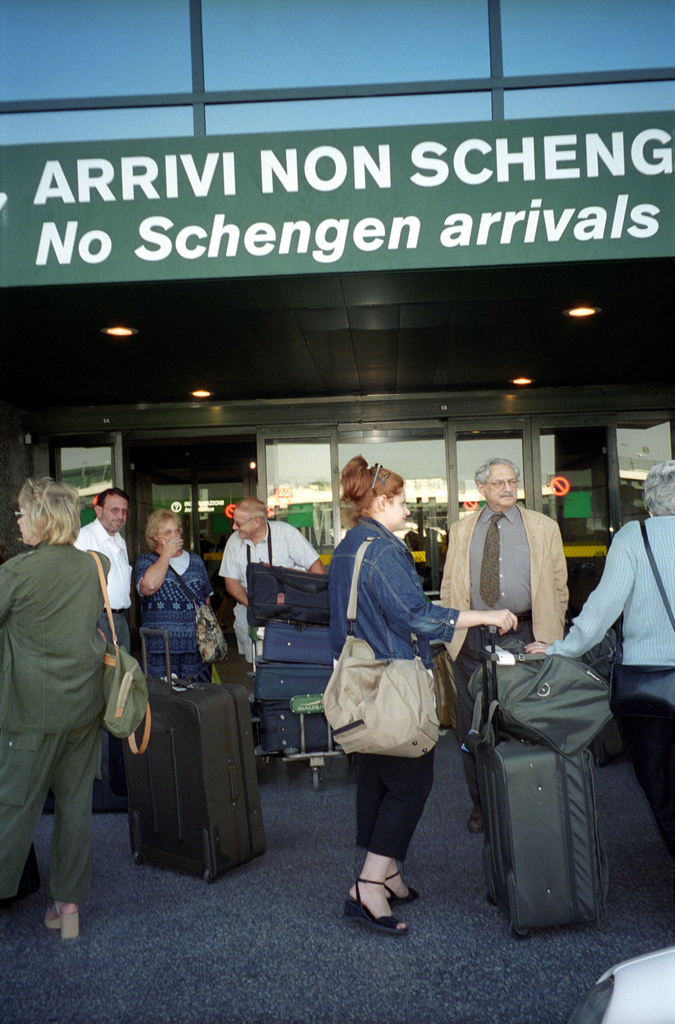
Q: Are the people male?
A: No, they are both male and female.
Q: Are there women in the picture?
A: Yes, there is a woman.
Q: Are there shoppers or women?
A: Yes, there is a woman.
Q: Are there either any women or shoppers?
A: Yes, there is a woman.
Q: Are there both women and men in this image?
A: Yes, there are both a woman and a man.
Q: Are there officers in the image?
A: No, there are no officers.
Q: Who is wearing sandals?
A: The woman is wearing sandals.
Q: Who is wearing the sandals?
A: The woman is wearing sandals.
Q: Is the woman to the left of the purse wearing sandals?
A: Yes, the woman is wearing sandals.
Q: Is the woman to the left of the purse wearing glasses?
A: No, the woman is wearing sandals.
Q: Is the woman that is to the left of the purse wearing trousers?
A: Yes, the woman is wearing trousers.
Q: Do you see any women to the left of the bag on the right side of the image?
A: Yes, there is a woman to the left of the purse.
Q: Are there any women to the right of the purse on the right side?
A: No, the woman is to the left of the purse.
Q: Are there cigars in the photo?
A: No, there are no cigars.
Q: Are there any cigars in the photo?
A: No, there are no cigars.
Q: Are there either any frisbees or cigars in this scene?
A: No, there are no cigars or frisbees.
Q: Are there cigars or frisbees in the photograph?
A: No, there are no cigars or frisbees.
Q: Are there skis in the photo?
A: No, there are no skis.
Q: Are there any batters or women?
A: Yes, there is a woman.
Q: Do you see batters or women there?
A: Yes, there is a woman.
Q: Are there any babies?
A: No, there are no babies.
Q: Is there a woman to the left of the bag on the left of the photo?
A: Yes, there is a woman to the left of the bag.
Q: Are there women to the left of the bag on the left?
A: Yes, there is a woman to the left of the bag.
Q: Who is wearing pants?
A: The woman is wearing pants.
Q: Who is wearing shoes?
A: The woman is wearing shoes.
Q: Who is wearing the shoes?
A: The woman is wearing shoes.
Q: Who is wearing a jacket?
A: The woman is wearing a jacket.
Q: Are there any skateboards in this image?
A: No, there are no skateboards.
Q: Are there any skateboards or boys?
A: No, there are no skateboards or boys.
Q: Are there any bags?
A: Yes, there is a bag.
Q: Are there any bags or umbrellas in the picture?
A: Yes, there is a bag.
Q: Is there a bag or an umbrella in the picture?
A: Yes, there is a bag.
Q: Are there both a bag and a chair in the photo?
A: No, there is a bag but no chairs.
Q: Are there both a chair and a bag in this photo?
A: No, there is a bag but no chairs.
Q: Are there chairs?
A: No, there are no chairs.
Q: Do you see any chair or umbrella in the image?
A: No, there are no chairs or umbrellas.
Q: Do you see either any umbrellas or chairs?
A: No, there are no chairs or umbrellas.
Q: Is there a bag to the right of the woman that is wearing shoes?
A: Yes, there is a bag to the right of the woman.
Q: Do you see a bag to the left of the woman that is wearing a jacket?
A: No, the bag is to the right of the woman.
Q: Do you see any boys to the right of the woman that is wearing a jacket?
A: No, there is a bag to the right of the woman.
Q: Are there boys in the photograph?
A: No, there are no boys.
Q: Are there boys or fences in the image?
A: No, there are no boys or fences.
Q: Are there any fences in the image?
A: No, there are no fences.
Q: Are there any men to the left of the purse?
A: Yes, there is a man to the left of the purse.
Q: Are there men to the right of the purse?
A: No, the man is to the left of the purse.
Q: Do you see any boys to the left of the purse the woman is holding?
A: No, there is a man to the left of the purse.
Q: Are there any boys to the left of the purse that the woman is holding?
A: No, there is a man to the left of the purse.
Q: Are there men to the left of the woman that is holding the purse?
A: Yes, there is a man to the left of the woman.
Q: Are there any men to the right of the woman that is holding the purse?
A: No, the man is to the left of the woman.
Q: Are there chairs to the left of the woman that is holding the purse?
A: No, there is a man to the left of the woman.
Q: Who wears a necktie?
A: The man wears a necktie.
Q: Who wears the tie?
A: The man wears a necktie.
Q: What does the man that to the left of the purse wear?
A: The man wears a tie.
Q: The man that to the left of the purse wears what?
A: The man wears a tie.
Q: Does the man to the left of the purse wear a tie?
A: Yes, the man wears a tie.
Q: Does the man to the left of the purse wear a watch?
A: No, the man wears a tie.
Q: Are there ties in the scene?
A: Yes, there is a tie.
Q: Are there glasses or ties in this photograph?
A: Yes, there is a tie.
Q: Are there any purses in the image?
A: Yes, there is a purse.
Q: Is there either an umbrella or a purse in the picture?
A: Yes, there is a purse.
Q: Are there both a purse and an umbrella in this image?
A: No, there is a purse but no umbrellas.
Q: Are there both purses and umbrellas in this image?
A: No, there is a purse but no umbrellas.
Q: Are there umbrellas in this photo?
A: No, there are no umbrellas.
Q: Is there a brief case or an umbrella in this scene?
A: No, there are no umbrellas or briefcases.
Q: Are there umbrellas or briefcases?
A: No, there are no umbrellas or briefcases.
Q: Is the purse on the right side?
A: Yes, the purse is on the right of the image.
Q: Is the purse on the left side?
A: No, the purse is on the right of the image.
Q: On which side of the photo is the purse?
A: The purse is on the right of the image.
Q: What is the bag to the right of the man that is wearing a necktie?
A: The bag is a purse.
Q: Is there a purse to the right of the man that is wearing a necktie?
A: Yes, there is a purse to the right of the man.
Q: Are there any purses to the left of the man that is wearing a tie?
A: No, the purse is to the right of the man.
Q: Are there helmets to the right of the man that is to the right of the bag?
A: No, there is a purse to the right of the man.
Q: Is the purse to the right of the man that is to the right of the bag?
A: Yes, the purse is to the right of the man.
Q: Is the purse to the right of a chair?
A: No, the purse is to the right of the man.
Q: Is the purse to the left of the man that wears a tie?
A: No, the purse is to the right of the man.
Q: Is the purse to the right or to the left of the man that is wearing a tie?
A: The purse is to the right of the man.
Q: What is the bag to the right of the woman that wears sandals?
A: The bag is a purse.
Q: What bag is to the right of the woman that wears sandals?
A: The bag is a purse.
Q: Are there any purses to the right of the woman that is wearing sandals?
A: Yes, there is a purse to the right of the woman.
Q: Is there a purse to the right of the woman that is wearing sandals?
A: Yes, there is a purse to the right of the woman.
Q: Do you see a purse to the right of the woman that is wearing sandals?
A: Yes, there is a purse to the right of the woman.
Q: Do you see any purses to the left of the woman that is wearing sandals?
A: No, the purse is to the right of the woman.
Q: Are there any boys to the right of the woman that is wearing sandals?
A: No, there is a purse to the right of the woman.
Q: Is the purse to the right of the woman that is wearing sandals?
A: Yes, the purse is to the right of the woman.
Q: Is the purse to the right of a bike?
A: No, the purse is to the right of the woman.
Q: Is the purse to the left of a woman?
A: No, the purse is to the right of a woman.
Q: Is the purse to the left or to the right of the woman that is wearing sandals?
A: The purse is to the right of the woman.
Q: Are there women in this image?
A: Yes, there is a woman.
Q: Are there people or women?
A: Yes, there is a woman.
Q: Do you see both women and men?
A: Yes, there are both a woman and a man.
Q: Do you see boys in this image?
A: No, there are no boys.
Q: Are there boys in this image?
A: No, there are no boys.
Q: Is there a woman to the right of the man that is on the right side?
A: Yes, there is a woman to the right of the man.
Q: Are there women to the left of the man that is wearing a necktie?
A: No, the woman is to the right of the man.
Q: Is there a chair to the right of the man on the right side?
A: No, there is a woman to the right of the man.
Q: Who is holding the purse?
A: The woman is holding the purse.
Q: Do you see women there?
A: Yes, there is a woman.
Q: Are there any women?
A: Yes, there is a woman.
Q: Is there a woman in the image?
A: Yes, there is a woman.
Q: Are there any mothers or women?
A: Yes, there is a woman.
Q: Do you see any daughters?
A: No, there are no daughters.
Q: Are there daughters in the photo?
A: No, there are no daughters.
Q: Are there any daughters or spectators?
A: No, there are no daughters or spectators.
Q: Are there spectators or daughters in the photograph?
A: No, there are no daughters or spectators.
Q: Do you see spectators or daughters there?
A: No, there are no daughters or spectators.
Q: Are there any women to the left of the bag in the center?
A: Yes, there is a woman to the left of the bag.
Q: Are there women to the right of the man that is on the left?
A: Yes, there is a woman to the right of the man.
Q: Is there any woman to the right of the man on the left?
A: Yes, there is a woman to the right of the man.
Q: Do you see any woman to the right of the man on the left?
A: Yes, there is a woman to the right of the man.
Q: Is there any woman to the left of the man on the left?
A: No, the woman is to the right of the man.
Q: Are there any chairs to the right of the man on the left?
A: No, there is a woman to the right of the man.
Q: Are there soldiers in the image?
A: No, there are no soldiers.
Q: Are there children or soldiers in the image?
A: No, there are no soldiers or children.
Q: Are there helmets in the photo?
A: No, there are no helmets.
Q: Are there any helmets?
A: No, there are no helmets.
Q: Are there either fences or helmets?
A: No, there are no fences or helmets.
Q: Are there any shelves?
A: No, there are no shelves.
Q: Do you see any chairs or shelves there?
A: No, there are no shelves or chairs.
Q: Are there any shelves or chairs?
A: No, there are no shelves or chairs.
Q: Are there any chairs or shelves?
A: No, there are no shelves or chairs.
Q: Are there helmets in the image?
A: No, there are no helmets.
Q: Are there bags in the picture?
A: Yes, there is a bag.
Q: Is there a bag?
A: Yes, there is a bag.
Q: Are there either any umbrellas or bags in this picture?
A: Yes, there is a bag.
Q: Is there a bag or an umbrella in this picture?
A: Yes, there is a bag.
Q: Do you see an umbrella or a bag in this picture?
A: Yes, there is a bag.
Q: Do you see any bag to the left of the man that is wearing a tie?
A: Yes, there is a bag to the left of the man.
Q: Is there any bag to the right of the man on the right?
A: No, the bag is to the left of the man.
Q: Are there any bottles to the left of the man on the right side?
A: No, there is a bag to the left of the man.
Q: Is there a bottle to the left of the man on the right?
A: No, there is a bag to the left of the man.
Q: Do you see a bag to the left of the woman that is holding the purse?
A: Yes, there is a bag to the left of the woman.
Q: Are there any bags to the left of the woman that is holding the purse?
A: Yes, there is a bag to the left of the woman.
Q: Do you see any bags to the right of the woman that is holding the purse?
A: No, the bag is to the left of the woman.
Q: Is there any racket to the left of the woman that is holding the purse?
A: No, there is a bag to the left of the woman.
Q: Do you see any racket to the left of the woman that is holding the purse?
A: No, there is a bag to the left of the woman.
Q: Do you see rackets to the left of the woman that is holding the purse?
A: No, there is a bag to the left of the woman.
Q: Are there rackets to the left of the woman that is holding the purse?
A: No, there is a bag to the left of the woman.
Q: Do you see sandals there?
A: Yes, there are sandals.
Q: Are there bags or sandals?
A: Yes, there are sandals.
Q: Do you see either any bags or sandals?
A: Yes, there are sandals.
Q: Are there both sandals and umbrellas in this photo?
A: No, there are sandals but no umbrellas.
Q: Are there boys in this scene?
A: No, there are no boys.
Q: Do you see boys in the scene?
A: No, there are no boys.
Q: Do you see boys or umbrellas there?
A: No, there are no boys or umbrellas.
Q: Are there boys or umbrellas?
A: No, there are no boys or umbrellas.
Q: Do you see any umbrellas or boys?
A: No, there are no boys or umbrellas.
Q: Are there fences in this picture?
A: No, there are no fences.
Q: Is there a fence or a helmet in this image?
A: No, there are no fences or helmets.